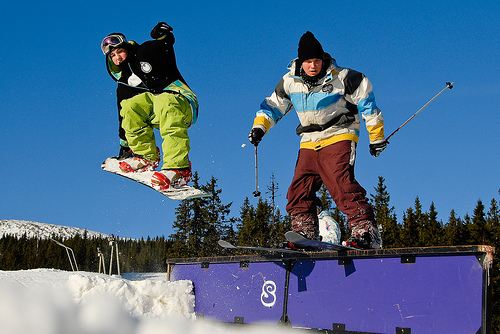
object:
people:
[99, 22, 385, 254]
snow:
[2, 268, 235, 333]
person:
[99, 22, 198, 191]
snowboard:
[102, 159, 211, 203]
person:
[250, 29, 384, 250]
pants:
[120, 80, 199, 170]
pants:
[286, 140, 380, 239]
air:
[3, 3, 497, 334]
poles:
[384, 81, 459, 142]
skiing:
[216, 230, 363, 253]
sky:
[2, 1, 497, 243]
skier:
[251, 32, 386, 250]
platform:
[164, 244, 494, 332]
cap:
[298, 32, 323, 66]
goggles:
[101, 35, 123, 55]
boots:
[150, 168, 192, 191]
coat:
[115, 34, 193, 146]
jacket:
[250, 52, 387, 148]